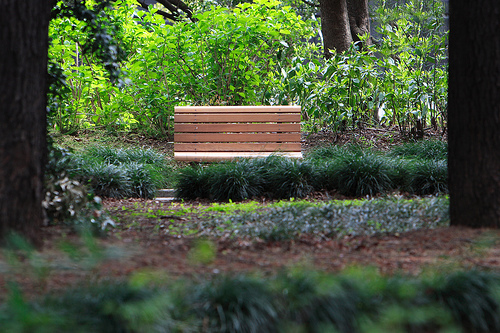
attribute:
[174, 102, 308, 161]
bench — wooden, wooden., empty, slatted, brown, large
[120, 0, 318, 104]
bush — large, green, wild, growing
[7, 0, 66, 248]
trunk — tall, large, black, brown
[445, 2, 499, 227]
trunk — tall, black, brown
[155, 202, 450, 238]
flowers — white, wild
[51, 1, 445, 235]
plants — wild, growing, green, small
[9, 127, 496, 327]
ground — green, covered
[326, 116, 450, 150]
sticks. — rotting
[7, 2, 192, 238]
tree — tall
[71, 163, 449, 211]
bushes — green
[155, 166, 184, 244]
path — rocky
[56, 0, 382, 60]
trees — green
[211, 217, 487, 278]
leaves — rotting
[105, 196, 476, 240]
grass — green, covered